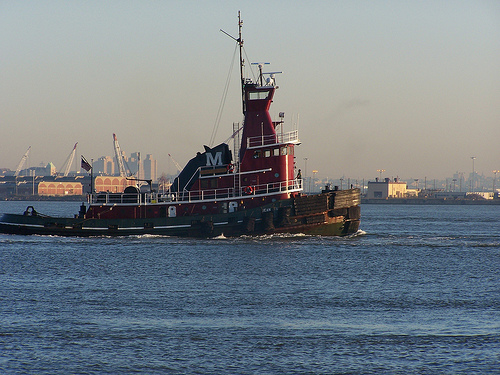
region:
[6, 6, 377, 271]
Big ship in the ocean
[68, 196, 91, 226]
Person stands in the ship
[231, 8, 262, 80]
Mast of ship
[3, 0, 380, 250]
Ship travels to the right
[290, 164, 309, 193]
Person in front of ship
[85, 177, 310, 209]
Rails of ship are white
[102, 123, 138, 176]
Crane in the harbor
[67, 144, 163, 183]
Tall buildings in the city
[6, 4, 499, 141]
Sky is blue and cloudy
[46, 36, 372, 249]
Ship is red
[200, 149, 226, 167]
A white letter M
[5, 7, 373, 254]
A red and black boat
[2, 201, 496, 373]
A blue body of water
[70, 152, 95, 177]
A American Flag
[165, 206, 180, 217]
A white door on a boat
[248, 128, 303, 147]
A white railing on a boat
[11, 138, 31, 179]
A white crane on land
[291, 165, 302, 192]
A person on a boat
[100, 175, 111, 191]
A arch shape on a building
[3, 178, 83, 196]
A red and tan building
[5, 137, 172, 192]
city in background behind water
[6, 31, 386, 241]
red fishing boat in ocean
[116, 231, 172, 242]
white foam created by boat moving through ocean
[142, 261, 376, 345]
blue ocean water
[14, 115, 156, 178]
white cranes along sea port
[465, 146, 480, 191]
tall lights in city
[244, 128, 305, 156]
white guard rails on fishing boat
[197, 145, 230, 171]
large white letter M on fishing boat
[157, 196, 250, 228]
two white doors on side of fishing boat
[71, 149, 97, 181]
flag on back of fishing boat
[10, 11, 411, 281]
boat on the water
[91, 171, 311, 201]
white railing on boat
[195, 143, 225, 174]
large M on boat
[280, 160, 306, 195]
person standing near white railing of boat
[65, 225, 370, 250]
water being stirred up by boat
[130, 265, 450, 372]
small waves on surface of the water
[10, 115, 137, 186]
cranes in the distance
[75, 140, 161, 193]
large buildings in the distance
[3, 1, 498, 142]
sky appears grey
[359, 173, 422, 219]
sun shining on side of building near water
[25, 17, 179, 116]
this is the sky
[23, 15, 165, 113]
the sky is clear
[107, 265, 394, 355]
this is the water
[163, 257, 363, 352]
the water is blue in color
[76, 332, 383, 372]
the water has some ripples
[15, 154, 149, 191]
these are some buildings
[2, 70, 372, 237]
this is a ship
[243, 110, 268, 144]
the ship is red in color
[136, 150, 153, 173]
the buildings are white in color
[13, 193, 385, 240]
the ship is moving on the water